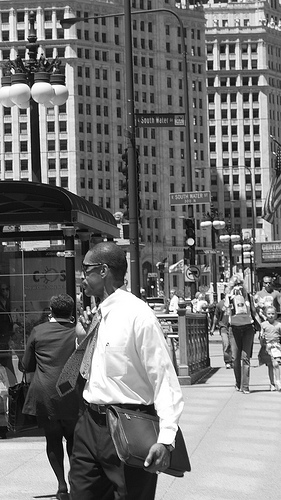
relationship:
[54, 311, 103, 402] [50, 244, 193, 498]
tie on man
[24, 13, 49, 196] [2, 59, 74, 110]
pole has lights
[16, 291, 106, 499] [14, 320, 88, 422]
person wears coat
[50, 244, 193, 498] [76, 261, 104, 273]
man wears glasses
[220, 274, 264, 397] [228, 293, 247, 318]
woman holds bag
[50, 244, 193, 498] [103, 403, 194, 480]
man carrying portfolio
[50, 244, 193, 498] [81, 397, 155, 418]
man wearing belt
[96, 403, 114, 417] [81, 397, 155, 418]
buckle on belt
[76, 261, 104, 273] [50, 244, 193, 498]
glasses on man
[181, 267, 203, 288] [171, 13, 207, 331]
sign on pole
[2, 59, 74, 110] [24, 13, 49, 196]
lights on pole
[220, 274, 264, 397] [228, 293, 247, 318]
woman carries bag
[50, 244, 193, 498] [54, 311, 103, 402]
man with tie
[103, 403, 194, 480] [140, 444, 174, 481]
portfolio in hand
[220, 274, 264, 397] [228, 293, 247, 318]
woman with bag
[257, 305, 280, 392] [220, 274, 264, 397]
people with woman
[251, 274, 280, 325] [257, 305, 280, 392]
man behind people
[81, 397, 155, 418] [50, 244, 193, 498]
belt worn by man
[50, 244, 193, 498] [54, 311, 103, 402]
man has dress tie